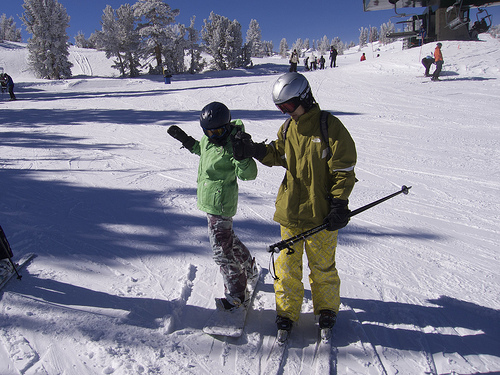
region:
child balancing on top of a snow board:
[163, 101, 276, 338]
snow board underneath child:
[203, 260, 264, 337]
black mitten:
[166, 125, 191, 147]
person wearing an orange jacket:
[433, 42, 445, 82]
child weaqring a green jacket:
[166, 101, 271, 307]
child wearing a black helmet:
[200, 100, 237, 143]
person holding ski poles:
[240, 72, 413, 343]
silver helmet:
[271, 70, 313, 108]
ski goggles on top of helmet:
[272, 84, 318, 114]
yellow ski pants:
[272, 223, 340, 318]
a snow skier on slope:
[245, 68, 407, 373]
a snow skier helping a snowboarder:
[165, 72, 415, 372]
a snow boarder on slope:
[169, 101, 262, 338]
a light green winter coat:
[195, 119, 260, 217]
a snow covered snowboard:
[201, 254, 262, 338]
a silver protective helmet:
[270, 73, 313, 115]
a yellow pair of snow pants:
[277, 227, 339, 318]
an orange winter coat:
[433, 46, 443, 62]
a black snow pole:
[262, 183, 413, 255]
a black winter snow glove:
[326, 197, 349, 231]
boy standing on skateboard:
[167, 100, 264, 340]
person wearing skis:
[246, 70, 356, 373]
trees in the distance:
[249, 20, 499, 58]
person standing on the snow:
[431, 41, 446, 81]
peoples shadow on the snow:
[339, 293, 499, 355]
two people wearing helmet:
[164, 71, 357, 342]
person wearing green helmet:
[165, 100, 259, 314]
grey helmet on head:
[271, 70, 313, 119]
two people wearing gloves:
[166, 70, 358, 342]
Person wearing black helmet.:
[198, 85, 229, 135]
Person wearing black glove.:
[163, 123, 183, 149]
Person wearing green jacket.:
[188, 135, 233, 206]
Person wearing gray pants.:
[202, 225, 246, 285]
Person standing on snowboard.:
[195, 257, 256, 347]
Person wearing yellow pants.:
[256, 244, 336, 305]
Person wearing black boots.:
[272, 310, 366, 327]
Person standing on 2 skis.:
[258, 321, 341, 370]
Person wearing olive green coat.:
[289, 138, 328, 213]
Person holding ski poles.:
[283, 219, 353, 257]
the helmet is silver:
[263, 77, 320, 108]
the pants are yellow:
[271, 233, 351, 312]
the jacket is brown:
[277, 127, 349, 214]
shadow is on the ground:
[365, 281, 498, 357]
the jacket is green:
[191, 98, 256, 218]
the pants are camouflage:
[203, 219, 273, 295]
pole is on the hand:
[283, 190, 418, 245]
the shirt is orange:
[429, 48, 451, 62]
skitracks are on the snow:
[421, 180, 471, 281]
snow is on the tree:
[109, 6, 184, 39]